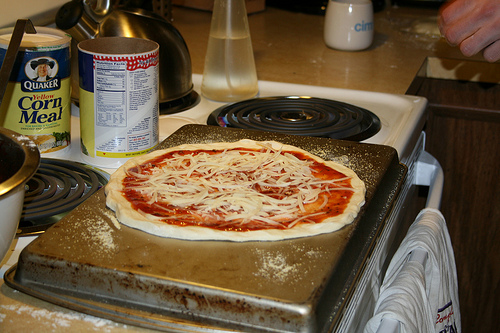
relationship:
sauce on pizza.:
[119, 146, 353, 236] [78, 114, 377, 264]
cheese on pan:
[102, 137, 367, 243] [4, 122, 408, 331]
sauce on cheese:
[317, 163, 355, 208] [102, 137, 367, 243]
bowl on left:
[0, 124, 50, 269] [2, 5, 59, 324]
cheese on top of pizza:
[102, 137, 367, 243] [109, 147, 369, 232]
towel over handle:
[370, 203, 461, 330] [403, 132, 449, 209]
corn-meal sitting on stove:
[0, 26, 73, 153] [24, 123, 413, 317]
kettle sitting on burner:
[56, 1, 201, 115] [205, 92, 376, 149]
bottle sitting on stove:
[199, 1, 261, 101] [197, 80, 419, 149]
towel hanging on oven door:
[364, 206, 462, 332] [349, 86, 455, 332]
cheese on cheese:
[102, 137, 367, 243] [102, 137, 367, 243]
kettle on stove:
[51, 1, 209, 117] [165, 71, 460, 328]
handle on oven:
[375, 144, 446, 332] [1, 71, 446, 331]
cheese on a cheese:
[131, 147, 343, 219] [102, 137, 367, 243]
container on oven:
[56, 26, 216, 237] [327, 93, 449, 330]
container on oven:
[76, 35, 161, 170] [1, 71, 446, 331]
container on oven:
[1, 26, 70, 153] [1, 71, 446, 331]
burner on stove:
[14, 155, 101, 234] [3, 73, 443, 330]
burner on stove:
[205, 94, 383, 142] [3, 73, 443, 330]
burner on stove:
[205, 94, 383, 142] [28, 59, 402, 329]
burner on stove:
[16, 156, 116, 237] [28, 59, 402, 329]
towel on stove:
[364, 206, 462, 332] [3, 73, 443, 330]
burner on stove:
[205, 92, 376, 149] [13, 12, 490, 267]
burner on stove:
[16, 156, 116, 237] [13, 12, 490, 267]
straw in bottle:
[220, 16, 232, 83] [206, 17, 259, 97]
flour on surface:
[79, 213, 122, 248] [28, 118, 392, 316]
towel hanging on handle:
[364, 206, 462, 332] [404, 132, 445, 212]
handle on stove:
[404, 132, 445, 212] [212, 54, 454, 193]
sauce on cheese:
[141, 193, 170, 212] [102, 137, 367, 243]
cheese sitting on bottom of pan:
[102, 137, 367, 243] [4, 122, 408, 331]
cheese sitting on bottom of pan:
[102, 137, 367, 243] [20, 186, 350, 331]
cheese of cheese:
[102, 137, 367, 243] [102, 137, 367, 243]